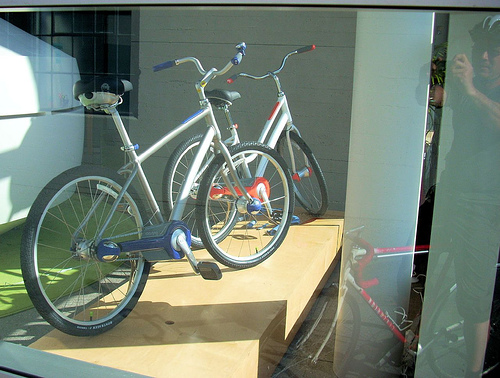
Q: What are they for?
A: Riding.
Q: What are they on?
A: Display.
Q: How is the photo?
A: Clear.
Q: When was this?
A: Daytime.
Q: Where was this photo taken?
A: In front of a window.